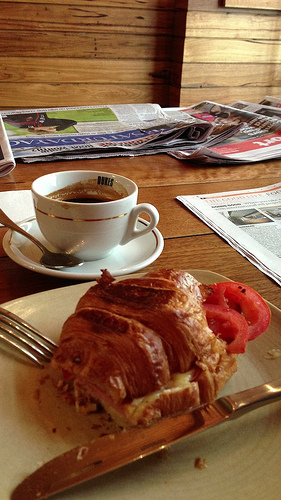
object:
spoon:
[0, 205, 85, 274]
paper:
[164, 93, 280, 173]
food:
[46, 265, 272, 433]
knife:
[7, 376, 280, 498]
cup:
[1, 168, 168, 290]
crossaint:
[34, 270, 240, 439]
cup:
[30, 163, 162, 265]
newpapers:
[149, 94, 280, 166]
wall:
[0, 0, 280, 104]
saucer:
[1, 212, 164, 277]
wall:
[0, 0, 277, 128]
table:
[0, 98, 281, 496]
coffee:
[45, 184, 128, 204]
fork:
[0, 307, 58, 373]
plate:
[1, 268, 279, 497]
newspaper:
[2, 94, 215, 164]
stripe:
[33, 206, 132, 224]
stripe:
[132, 215, 160, 264]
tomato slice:
[200, 298, 249, 356]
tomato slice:
[206, 275, 272, 342]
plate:
[2, 208, 168, 283]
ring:
[36, 205, 137, 227]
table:
[165, 212, 188, 260]